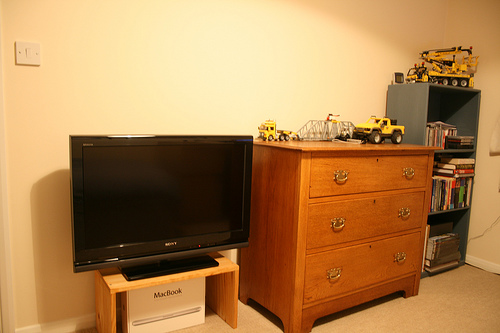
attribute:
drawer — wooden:
[302, 229, 424, 299]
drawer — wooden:
[311, 191, 433, 239]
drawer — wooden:
[313, 247, 423, 301]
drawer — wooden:
[310, 200, 428, 230]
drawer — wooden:
[320, 166, 430, 185]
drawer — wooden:
[317, 163, 430, 190]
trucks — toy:
[352, 109, 411, 144]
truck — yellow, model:
[412, 49, 476, 83]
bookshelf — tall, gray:
[388, 78, 472, 269]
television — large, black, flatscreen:
[66, 132, 256, 274]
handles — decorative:
[321, 205, 413, 232]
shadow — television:
[11, 149, 71, 309]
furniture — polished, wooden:
[254, 143, 438, 317]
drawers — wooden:
[311, 153, 423, 285]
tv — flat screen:
[55, 140, 276, 275]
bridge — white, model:
[268, 118, 369, 177]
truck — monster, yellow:
[423, 40, 477, 87]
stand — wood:
[97, 267, 247, 329]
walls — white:
[165, 9, 316, 99]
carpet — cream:
[422, 294, 478, 318]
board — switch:
[6, 42, 38, 65]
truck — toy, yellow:
[257, 120, 287, 145]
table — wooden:
[105, 278, 127, 293]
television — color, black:
[72, 127, 260, 261]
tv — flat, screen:
[78, 138, 263, 247]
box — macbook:
[128, 276, 219, 326]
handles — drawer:
[334, 167, 368, 186]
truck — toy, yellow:
[254, 114, 284, 144]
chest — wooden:
[293, 140, 418, 282]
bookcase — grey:
[438, 84, 484, 265]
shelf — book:
[415, 86, 432, 139]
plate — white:
[15, 42, 44, 61]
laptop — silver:
[136, 290, 213, 328]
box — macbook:
[123, 289, 217, 331]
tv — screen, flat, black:
[77, 135, 243, 272]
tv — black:
[67, 132, 254, 273]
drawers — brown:
[301, 153, 429, 304]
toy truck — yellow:
[350, 113, 407, 143]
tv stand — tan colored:
[93, 249, 241, 331]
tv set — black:
[67, 132, 255, 274]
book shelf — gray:
[382, 80, 480, 276]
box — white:
[122, 268, 214, 331]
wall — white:
[1, 6, 442, 331]